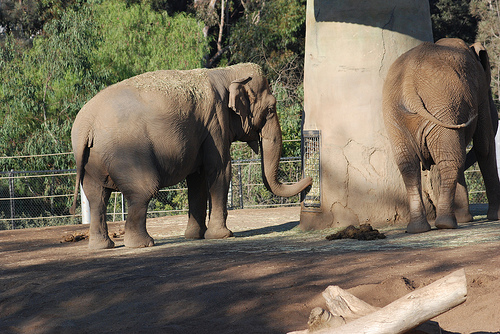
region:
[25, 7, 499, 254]
Two large elephants at the zoo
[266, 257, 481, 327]
A fallen tree branch on the ground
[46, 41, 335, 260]
Elephant eating hay from the feeder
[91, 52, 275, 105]
Hay on the elephants head and back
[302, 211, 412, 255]
Elephant dung on the ground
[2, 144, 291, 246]
Fencing containing the elephants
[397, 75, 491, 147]
Elephants tail swinging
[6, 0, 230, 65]
Green trees growing along the enclosure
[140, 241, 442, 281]
Hay and dirt on the ground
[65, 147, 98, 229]
White fence post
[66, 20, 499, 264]
these are two elephants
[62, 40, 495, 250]
the elephants arewaking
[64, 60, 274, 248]
this elephant is fat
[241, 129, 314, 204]
its trunk is coiled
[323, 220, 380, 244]
this is the elephants dung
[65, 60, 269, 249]
this elephant is dusty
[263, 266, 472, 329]
a log is beside the elephants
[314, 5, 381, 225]
the pillar is wide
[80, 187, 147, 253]
the elephant has short legs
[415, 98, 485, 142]
the tail is on the side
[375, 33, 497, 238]
The elephant on the right side.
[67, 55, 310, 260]
The elephant on the left side.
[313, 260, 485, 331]
Broken logs on the ground.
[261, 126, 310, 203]
The elephants trunk.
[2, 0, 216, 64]
Green trees in the background.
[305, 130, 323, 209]
A metal fence.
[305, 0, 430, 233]
A large tree structure.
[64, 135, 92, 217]
The elephants tail.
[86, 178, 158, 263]
The elephants back two legs.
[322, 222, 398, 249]
A pile of elephant feces.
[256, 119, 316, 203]
An adult elephant's curled trunk.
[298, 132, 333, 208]
A secured feed compartment.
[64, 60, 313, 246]
A feeding adult elephant.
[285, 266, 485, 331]
A downed piece of a tree.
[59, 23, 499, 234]
Two adult elephants milling about a large structure.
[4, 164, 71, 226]
A section of security fence.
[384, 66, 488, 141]
The swinging tail of an adult elephant.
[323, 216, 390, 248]
A pile of elephant dung.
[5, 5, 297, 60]
Trees rising behind a security fence.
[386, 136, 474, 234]
An adult elephant's rear legs.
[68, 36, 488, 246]
Two elephants on the ground.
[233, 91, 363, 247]
Trunk on the elephant.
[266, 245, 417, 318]
Wood on the ground.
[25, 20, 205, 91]
Green trees in the background.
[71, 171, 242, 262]
Four elephant feet on the ground.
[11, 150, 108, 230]
Fence behind the elephant.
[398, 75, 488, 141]
Elephant's tail.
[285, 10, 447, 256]
Pole beside the elephants.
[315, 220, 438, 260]
Elephant excrement on the ground.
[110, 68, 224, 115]
Dirt on the elephant's back.